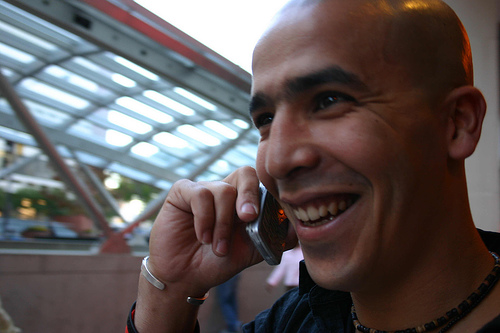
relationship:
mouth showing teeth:
[253, 172, 387, 259] [275, 187, 353, 244]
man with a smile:
[134, 10, 497, 327] [270, 182, 373, 249]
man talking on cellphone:
[134, 10, 497, 327] [243, 182, 290, 266]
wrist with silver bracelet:
[136, 254, 208, 317] [135, 254, 210, 307]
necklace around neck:
[417, 265, 487, 332] [330, 153, 496, 331]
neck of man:
[330, 153, 496, 331] [134, 10, 497, 327]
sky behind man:
[0, 0, 293, 228] [134, 10, 497, 327]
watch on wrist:
[138, 255, 208, 305] [122, 250, 217, 318]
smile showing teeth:
[267, 180, 381, 240] [295, 204, 330, 221]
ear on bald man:
[448, 85, 486, 160] [123, 0, 498, 331]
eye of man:
[300, 81, 368, 131] [134, 10, 497, 327]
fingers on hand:
[222, 162, 262, 223] [143, 162, 298, 299]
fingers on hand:
[206, 173, 241, 257] [143, 162, 298, 299]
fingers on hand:
[173, 177, 214, 244] [143, 162, 298, 299]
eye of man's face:
[300, 81, 368, 131] [230, 65, 359, 260]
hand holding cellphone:
[139, 161, 306, 295] [243, 182, 290, 266]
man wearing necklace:
[134, 10, 497, 327] [432, 270, 478, 322]